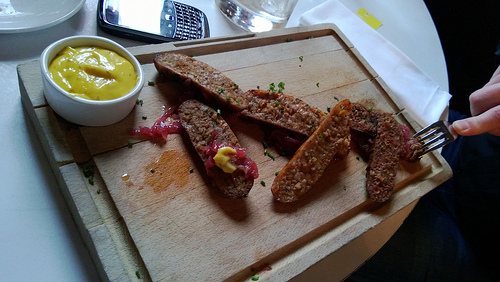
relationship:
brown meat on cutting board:
[153, 50, 425, 208] [34, 34, 457, 277]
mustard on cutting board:
[42, 37, 139, 97] [34, 34, 457, 277]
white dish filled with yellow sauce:
[36, 22, 144, 127] [53, 37, 136, 99]